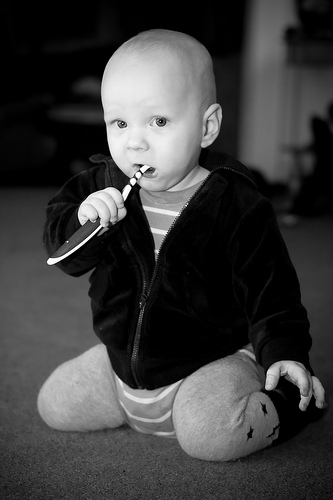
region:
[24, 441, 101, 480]
the floor is clean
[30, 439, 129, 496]
the floor is grey in color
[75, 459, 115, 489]
the floor has a carpet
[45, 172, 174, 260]
this is a toothbrush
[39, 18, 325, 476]
this is a baby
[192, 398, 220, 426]
the cloth is grey in color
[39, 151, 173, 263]
the brush is in the mouth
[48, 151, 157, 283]
the baby is holding the toothbrush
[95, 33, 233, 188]
head of a person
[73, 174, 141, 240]
hand of a person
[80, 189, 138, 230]
finger of a person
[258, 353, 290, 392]
thumb of a person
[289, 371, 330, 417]
finger of a person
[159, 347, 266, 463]
thigh of a person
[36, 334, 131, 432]
thigh of a person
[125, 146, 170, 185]
mouth of a person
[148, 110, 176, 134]
an eye of a person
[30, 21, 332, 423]
This is a boy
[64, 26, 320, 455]
This is a boy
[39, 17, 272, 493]
This is a boyThis is a boy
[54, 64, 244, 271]
the baby is brushing teeth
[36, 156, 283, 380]
the baby is wearing a jacket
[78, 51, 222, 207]
the baby is bald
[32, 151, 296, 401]
the jacket is black